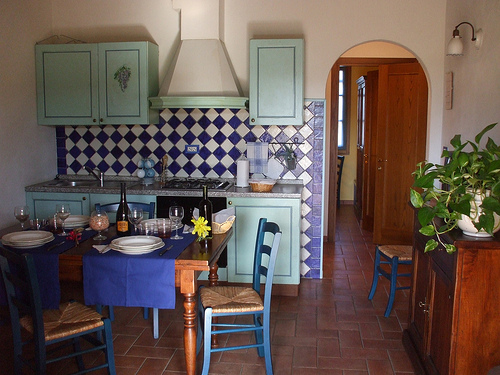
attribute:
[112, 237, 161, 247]
plate — white, sitting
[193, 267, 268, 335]
chair — wooden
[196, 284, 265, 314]
seat — tan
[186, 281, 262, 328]
seat — blue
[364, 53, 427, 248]
doors — brown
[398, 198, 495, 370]
cupboard — wooden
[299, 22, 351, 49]
wall — blue, white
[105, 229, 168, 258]
plates — white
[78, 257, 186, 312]
table cloth — blue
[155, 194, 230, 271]
oven — steel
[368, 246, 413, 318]
legs — blue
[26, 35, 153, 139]
drawers — light blue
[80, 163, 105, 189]
tap — silver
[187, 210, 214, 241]
flower — yellow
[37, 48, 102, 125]
cabinet — blue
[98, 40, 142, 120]
cabinet — blue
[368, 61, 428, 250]
door — open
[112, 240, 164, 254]
plate — white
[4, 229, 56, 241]
plate — white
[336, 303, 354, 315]
tile — brown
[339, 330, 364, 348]
tile — brown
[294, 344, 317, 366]
tile — brown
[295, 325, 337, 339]
tile — brown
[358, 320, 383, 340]
tile — brown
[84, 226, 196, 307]
cloth — blue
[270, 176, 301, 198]
counter — marbled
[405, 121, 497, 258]
flower — green 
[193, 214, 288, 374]
chair — blue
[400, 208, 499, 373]
stand — brown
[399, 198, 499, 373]
cabinet — wooden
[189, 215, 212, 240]
flower — yellow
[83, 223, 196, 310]
table mat — blue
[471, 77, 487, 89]
wall — light pink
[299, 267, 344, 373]
floor — brown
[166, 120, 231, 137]
wall — white, blue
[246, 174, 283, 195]
basket — brown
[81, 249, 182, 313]
table mat — blue